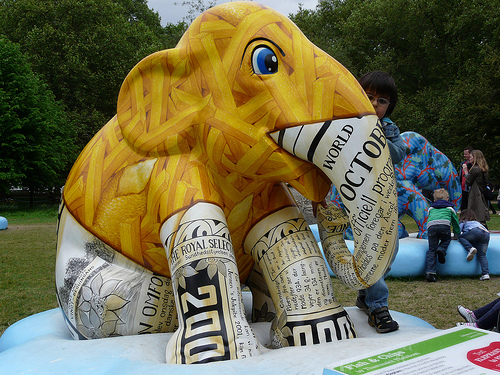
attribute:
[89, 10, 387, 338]
elephant — yellow, large, brown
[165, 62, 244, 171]
pattern — french fries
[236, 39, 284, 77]
eyes — blue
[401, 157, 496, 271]
kids — climbing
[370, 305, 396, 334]
shoe — gray, black, part, side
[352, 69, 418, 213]
boy — green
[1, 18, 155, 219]
trees — green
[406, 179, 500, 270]
children — climbing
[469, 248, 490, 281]
shoes — white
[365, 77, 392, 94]
hair — brown, dark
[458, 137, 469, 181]
man — back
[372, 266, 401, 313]
jeans — blue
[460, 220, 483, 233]
shirt — purple, red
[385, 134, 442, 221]
elephant — blue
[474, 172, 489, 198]
coat — black, gray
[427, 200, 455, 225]
hoodie — blue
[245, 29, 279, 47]
eyebrow — black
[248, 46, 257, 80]
eyelashes — black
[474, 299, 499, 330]
pants — blue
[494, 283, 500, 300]
book — part, edge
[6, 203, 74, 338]
lawn — part